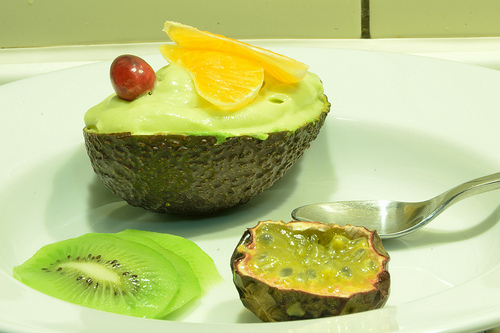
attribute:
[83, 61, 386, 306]
fruits — passion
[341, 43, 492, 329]
plate — white, centered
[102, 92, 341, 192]
avocado — half, bumpy, baked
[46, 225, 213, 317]
kiwi — sliced, rotting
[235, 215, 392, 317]
fruit — cut, green, mushy, half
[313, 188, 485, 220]
spoon — silver, steel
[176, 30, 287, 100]
orange — sliced, segments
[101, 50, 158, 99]
grape — red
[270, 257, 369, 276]
seeds — black, dark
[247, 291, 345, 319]
skin — mottled, bumpy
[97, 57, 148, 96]
olive — single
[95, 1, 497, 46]
wall — tiled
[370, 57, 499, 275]
bowl — white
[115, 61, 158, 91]
cherry — red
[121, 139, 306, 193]
skin — green